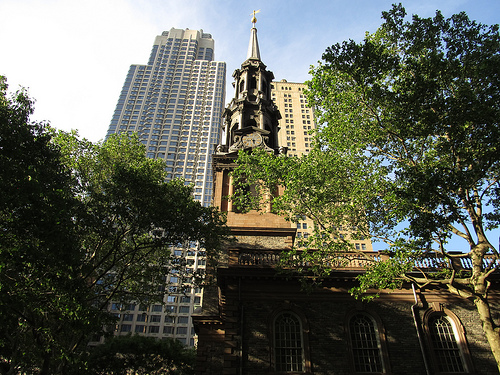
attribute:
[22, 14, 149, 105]
clouds — white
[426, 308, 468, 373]
window — exterior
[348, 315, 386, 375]
window — exterior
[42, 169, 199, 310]
trees — green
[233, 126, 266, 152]
clock — white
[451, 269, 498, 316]
tree trunk — brown 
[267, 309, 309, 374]
window — circular 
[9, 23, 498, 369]
trees — green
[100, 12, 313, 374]
skyscraper — brown, tall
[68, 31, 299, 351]
building — windowed, high-rise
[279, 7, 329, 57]
sky — blue, white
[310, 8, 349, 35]
sky — blue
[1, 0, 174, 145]
cloud — white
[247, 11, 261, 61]
top — pointed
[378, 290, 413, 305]
exterior — brown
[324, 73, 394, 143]
leaves — bright green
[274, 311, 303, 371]
window — wood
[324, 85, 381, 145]
leaves — green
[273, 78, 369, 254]
building — light brown, modern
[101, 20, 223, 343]
building — modern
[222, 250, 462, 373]
building — old